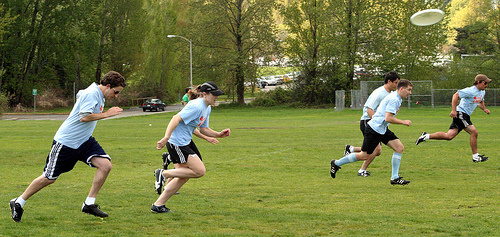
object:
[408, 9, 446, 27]
frisbee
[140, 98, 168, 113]
car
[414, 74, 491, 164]
man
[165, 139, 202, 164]
short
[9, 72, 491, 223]
people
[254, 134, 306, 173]
grass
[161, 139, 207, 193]
pant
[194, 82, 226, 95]
cap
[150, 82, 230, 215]
female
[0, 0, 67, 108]
tree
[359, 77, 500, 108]
fence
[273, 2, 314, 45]
sky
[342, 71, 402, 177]
men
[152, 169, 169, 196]
foot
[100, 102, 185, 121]
street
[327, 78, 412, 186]
athlete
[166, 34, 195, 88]
light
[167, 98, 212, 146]
shirt